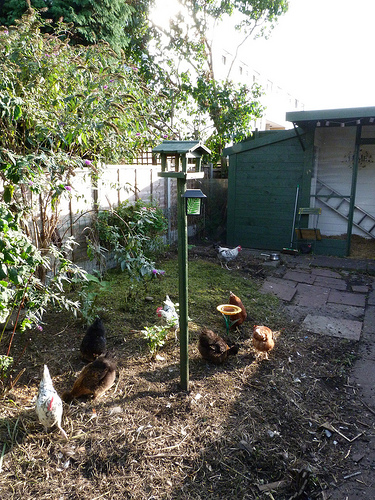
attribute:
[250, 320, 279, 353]
chicken — dark, golden, white, brown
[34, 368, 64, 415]
chicken — white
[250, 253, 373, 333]
sidewalk — brick, disrepair, stone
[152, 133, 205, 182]
feeder — house shaped, green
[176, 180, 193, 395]
pole — green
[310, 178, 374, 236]
ladder — metal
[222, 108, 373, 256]
building — green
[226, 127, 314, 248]
chicken coop — green, white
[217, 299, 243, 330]
pot — yellow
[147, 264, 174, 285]
flowers — purple, growing